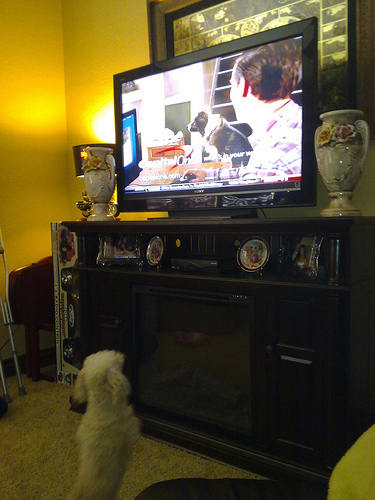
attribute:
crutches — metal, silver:
[0, 229, 36, 411]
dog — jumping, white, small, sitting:
[59, 336, 161, 497]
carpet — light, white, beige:
[11, 414, 64, 470]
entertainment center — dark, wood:
[57, 216, 374, 497]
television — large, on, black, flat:
[103, 21, 328, 208]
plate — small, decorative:
[231, 235, 268, 278]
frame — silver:
[280, 230, 329, 279]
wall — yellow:
[1, 117, 61, 252]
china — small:
[143, 234, 164, 271]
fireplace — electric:
[131, 286, 267, 441]